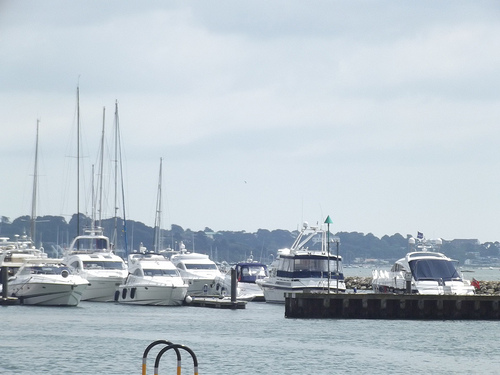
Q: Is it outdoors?
A: Yes, it is outdoors.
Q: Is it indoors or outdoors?
A: It is outdoors.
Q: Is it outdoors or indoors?
A: It is outdoors.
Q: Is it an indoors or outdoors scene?
A: It is outdoors.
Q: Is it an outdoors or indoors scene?
A: It is outdoors.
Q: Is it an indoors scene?
A: No, it is outdoors.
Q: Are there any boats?
A: Yes, there is a boat.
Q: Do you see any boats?
A: Yes, there is a boat.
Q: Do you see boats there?
A: Yes, there is a boat.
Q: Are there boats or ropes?
A: Yes, there is a boat.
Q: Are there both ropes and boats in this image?
A: No, there is a boat but no ropes.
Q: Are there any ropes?
A: No, there are no ropes.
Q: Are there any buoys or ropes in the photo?
A: No, there are no ropes or buoys.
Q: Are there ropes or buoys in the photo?
A: No, there are no ropes or buoys.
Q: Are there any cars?
A: No, there are no cars.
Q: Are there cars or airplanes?
A: No, there are no cars or airplanes.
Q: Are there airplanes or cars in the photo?
A: No, there are no cars or airplanes.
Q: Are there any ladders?
A: No, there are no ladders.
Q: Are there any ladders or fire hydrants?
A: No, there are no ladders or fire hydrants.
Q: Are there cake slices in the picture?
A: No, there are no cake slices.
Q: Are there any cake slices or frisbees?
A: No, there are no cake slices or frisbees.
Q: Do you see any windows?
A: Yes, there is a window.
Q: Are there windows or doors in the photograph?
A: Yes, there is a window.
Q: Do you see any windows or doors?
A: Yes, there is a window.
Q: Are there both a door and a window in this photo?
A: No, there is a window but no doors.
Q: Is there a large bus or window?
A: Yes, there is a large window.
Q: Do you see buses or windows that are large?
A: Yes, the window is large.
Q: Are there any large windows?
A: Yes, there is a large window.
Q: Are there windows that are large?
A: Yes, there is a window that is large.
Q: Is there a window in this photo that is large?
A: Yes, there is a window that is large.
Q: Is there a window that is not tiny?
A: Yes, there is a large window.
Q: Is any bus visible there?
A: No, there are no buses.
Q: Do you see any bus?
A: No, there are no buses.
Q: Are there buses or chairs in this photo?
A: No, there are no buses or chairs.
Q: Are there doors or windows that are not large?
A: No, there is a window but it is large.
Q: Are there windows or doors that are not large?
A: No, there is a window but it is large.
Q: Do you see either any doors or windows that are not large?
A: No, there is a window but it is large.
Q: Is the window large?
A: Yes, the window is large.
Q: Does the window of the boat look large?
A: Yes, the window is large.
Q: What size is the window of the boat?
A: The window is large.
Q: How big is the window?
A: The window is large.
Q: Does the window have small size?
A: No, the window is large.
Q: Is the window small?
A: No, the window is large.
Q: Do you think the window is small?
A: No, the window is large.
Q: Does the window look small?
A: No, the window is large.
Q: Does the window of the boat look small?
A: No, the window is large.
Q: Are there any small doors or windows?
A: No, there is a window but it is large.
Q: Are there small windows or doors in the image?
A: No, there is a window but it is large.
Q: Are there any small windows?
A: No, there is a window but it is large.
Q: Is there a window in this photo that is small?
A: No, there is a window but it is large.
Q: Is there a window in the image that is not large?
A: No, there is a window but it is large.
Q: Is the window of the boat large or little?
A: The window is large.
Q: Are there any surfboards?
A: No, there are no surfboards.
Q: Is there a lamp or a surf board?
A: No, there are no surfboards or lamps.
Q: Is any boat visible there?
A: Yes, there is a boat.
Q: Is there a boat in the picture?
A: Yes, there is a boat.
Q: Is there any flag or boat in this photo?
A: Yes, there is a boat.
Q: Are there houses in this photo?
A: No, there are no houses.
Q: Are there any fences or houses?
A: No, there are no houses or fences.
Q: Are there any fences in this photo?
A: No, there are no fences.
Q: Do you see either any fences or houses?
A: No, there are no fences or houses.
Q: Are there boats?
A: Yes, there is a boat.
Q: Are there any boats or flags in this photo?
A: Yes, there is a boat.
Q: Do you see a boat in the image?
A: Yes, there is a boat.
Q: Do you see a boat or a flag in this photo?
A: Yes, there is a boat.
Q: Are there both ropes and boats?
A: No, there is a boat but no ropes.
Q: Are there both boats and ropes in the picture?
A: No, there is a boat but no ropes.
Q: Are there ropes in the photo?
A: No, there are no ropes.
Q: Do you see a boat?
A: Yes, there is a boat.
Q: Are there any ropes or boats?
A: Yes, there is a boat.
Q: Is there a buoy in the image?
A: No, there are no buoys.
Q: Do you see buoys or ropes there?
A: No, there are no buoys or ropes.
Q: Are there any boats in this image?
A: Yes, there is a boat.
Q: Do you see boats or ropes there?
A: Yes, there is a boat.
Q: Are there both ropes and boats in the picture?
A: No, there is a boat but no ropes.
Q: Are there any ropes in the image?
A: No, there are no ropes.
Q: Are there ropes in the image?
A: No, there are no ropes.